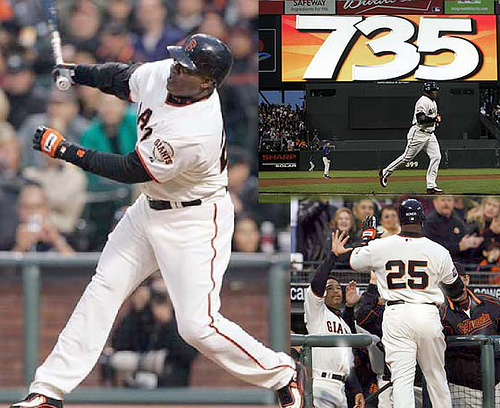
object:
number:
[283, 14, 497, 80]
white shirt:
[304, 289, 356, 384]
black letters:
[322, 317, 348, 335]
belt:
[140, 187, 222, 210]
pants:
[386, 125, 448, 187]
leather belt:
[140, 190, 207, 215]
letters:
[132, 99, 175, 168]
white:
[399, 243, 420, 255]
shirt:
[351, 241, 453, 301]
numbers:
[381, 256, 428, 293]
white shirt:
[130, 65, 229, 205]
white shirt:
[412, 94, 442, 134]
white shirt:
[345, 226, 463, 305]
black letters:
[132, 100, 173, 170]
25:
[372, 253, 433, 293]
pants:
[27, 188, 297, 395]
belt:
[381, 288, 446, 318]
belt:
[410, 117, 434, 135]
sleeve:
[62, 138, 153, 185]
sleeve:
[76, 58, 141, 98]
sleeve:
[310, 251, 337, 296]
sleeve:
[415, 110, 436, 125]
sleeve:
[437, 275, 465, 299]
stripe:
[204, 197, 262, 369]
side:
[205, 173, 298, 374]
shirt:
[131, 59, 235, 203]